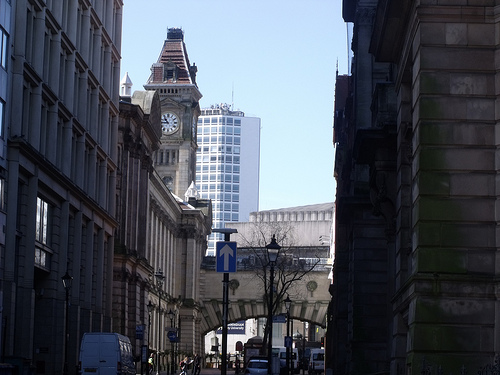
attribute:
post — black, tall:
[201, 217, 249, 374]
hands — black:
[162, 116, 179, 134]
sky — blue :
[120, 0, 346, 212]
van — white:
[64, 320, 144, 367]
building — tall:
[134, 36, 201, 216]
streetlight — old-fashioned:
[194, 229, 319, 369]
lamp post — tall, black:
[263, 232, 284, 370]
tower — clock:
[126, 44, 200, 179]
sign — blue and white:
[214, 235, 239, 277]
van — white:
[80, 330, 145, 373]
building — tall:
[188, 103, 263, 258]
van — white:
[284, 329, 297, 365]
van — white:
[308, 345, 328, 370]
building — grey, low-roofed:
[240, 204, 335, 245]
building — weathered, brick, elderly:
[322, 0, 499, 374]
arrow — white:
[219, 244, 233, 271]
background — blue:
[216, 241, 236, 271]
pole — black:
[202, 221, 263, 368]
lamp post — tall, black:
[163, 306, 184, 374]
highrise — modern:
[194, 110, 263, 248]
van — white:
[75, 327, 139, 373]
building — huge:
[17, 5, 143, 351]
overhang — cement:
[211, 230, 334, 336]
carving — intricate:
[183, 245, 299, 341]